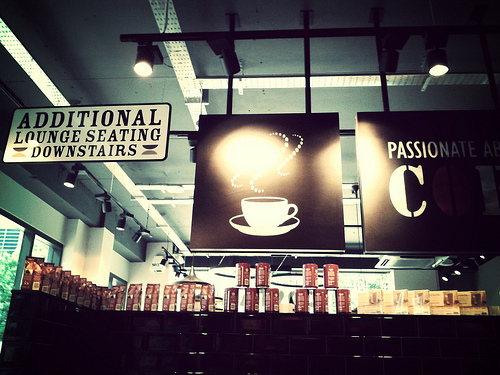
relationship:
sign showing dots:
[187, 106, 347, 250] [230, 126, 304, 191]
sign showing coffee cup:
[187, 106, 347, 250] [230, 193, 306, 235]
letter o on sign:
[27, 130, 33, 143] [5, 105, 173, 162]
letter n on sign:
[118, 105, 131, 128] [5, 105, 173, 162]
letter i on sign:
[92, 107, 99, 129] [0, 99, 175, 168]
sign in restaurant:
[4, 102, 174, 165] [2, 5, 482, 373]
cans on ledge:
[222, 261, 282, 314] [15, 310, 484, 326]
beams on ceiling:
[0, 25, 64, 112] [2, 2, 494, 269]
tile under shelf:
[108, 320, 475, 372] [109, 307, 476, 322]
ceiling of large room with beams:
[49, 53, 449, 117] [300, 165, 352, 202]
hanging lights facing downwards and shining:
[114, 57, 451, 113] [184, 186, 218, 204]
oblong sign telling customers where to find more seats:
[13, 98, 173, 194] [41, 342, 178, 375]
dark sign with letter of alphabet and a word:
[357, 115, 468, 253] [408, 187, 435, 203]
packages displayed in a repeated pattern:
[349, 259, 486, 342] [372, 304, 422, 362]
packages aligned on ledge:
[98, 263, 208, 330] [0, 289, 483, 375]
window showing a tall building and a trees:
[1, 229, 21, 351] [0, 253, 15, 325]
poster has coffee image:
[187, 112, 344, 254] [227, 127, 310, 236]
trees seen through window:
[0, 253, 23, 325] [0, 207, 30, 347]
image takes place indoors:
[184, 111, 344, 258] [6, 6, 489, 368]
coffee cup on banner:
[223, 191, 304, 240] [185, 108, 343, 264]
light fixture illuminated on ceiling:
[126, 40, 166, 81] [2, 2, 494, 269]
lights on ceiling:
[54, 170, 155, 246] [2, 2, 494, 269]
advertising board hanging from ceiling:
[354, 0, 497, 258] [2, 2, 494, 269]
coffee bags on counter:
[21, 257, 216, 311] [2, 287, 497, 370]